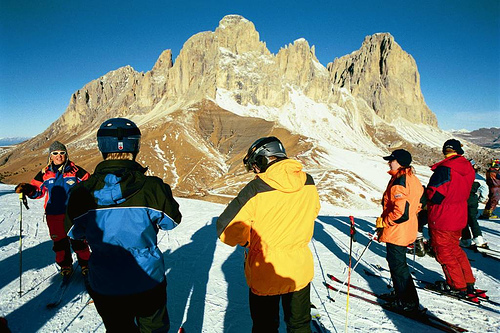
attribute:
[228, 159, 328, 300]
jacket — yellow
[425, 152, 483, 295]
outfit — red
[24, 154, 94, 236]
jacket — red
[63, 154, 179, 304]
jacket — black, blue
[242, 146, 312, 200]
hood — yellow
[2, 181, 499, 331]
snow — white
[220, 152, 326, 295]
jacket — yellow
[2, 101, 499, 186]
clouds — white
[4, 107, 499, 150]
clouds — white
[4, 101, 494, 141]
clouds — white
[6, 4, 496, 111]
sky — blue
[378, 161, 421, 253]
jacket — orange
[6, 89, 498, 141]
clouds — white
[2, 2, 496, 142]
sky — blue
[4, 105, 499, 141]
clouds — white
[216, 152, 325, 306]
coat — black, yellow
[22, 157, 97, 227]
coat — red, blue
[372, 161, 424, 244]
coat — black, orange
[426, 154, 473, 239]
coat — red, black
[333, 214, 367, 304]
pole — yellow, orange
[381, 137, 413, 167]
hat — black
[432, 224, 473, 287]
pants — red